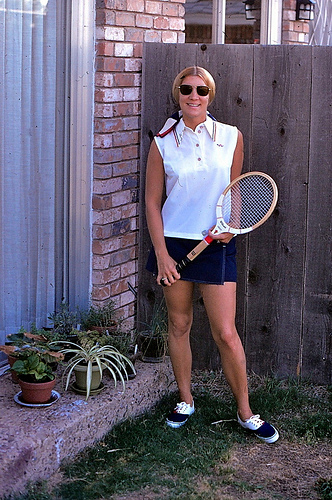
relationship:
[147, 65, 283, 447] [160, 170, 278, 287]
female holding tennis racket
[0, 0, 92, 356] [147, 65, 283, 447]
door next to female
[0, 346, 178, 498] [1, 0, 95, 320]
stoop in front of door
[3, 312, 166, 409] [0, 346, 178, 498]
potted plants top of stoop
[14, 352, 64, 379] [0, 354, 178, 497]
plant sitting on step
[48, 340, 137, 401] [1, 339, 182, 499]
plants sitting on step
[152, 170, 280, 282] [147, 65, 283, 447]
racket held by female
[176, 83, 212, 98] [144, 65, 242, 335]
sunglasses worn by girl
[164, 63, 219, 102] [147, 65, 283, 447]
hair on female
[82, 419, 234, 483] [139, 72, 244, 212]
grass front of girl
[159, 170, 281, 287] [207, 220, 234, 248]
racket in hand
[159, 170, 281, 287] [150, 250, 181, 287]
racket in hand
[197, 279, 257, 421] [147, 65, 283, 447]
left leg of female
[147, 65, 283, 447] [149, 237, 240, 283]
female wearing skirt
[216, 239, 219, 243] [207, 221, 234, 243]
ring on hand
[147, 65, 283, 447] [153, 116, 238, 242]
female wearing shirt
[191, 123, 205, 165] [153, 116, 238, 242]
buttons on shirt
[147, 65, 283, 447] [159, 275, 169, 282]
female wearing ring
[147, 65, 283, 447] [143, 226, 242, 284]
female in skirt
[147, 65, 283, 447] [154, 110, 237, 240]
female in shirt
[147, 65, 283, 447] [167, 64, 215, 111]
female with hair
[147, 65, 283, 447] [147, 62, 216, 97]
female has hair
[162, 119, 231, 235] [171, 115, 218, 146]
shirt has collar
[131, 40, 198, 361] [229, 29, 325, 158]
plank in fence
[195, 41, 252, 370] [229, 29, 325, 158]
plank in fence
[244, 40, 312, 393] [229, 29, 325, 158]
plank in fence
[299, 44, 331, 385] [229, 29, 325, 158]
plank in fence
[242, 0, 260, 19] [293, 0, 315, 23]
reflection of light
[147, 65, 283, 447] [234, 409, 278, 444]
female wearing shoe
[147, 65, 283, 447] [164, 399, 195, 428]
female wearing shoe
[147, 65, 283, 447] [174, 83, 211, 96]
female wearing sunglasses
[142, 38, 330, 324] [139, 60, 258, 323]
fence behind girl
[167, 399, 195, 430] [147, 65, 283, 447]
shoe of female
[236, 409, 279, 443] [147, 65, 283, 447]
shoe of female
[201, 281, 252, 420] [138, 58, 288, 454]
left leg of lady